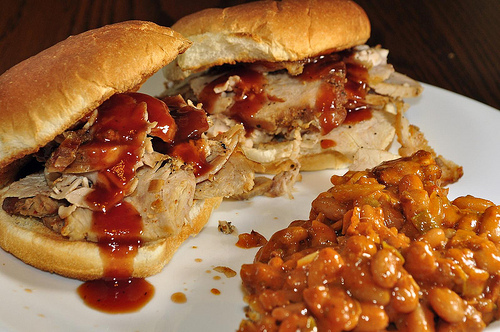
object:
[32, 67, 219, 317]
bbq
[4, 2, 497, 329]
dinner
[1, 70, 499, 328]
plate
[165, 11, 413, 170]
sandwich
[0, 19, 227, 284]
sandwich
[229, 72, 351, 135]
bbq pork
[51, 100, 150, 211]
bbq pork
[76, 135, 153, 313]
barbecue sauce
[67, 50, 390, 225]
meat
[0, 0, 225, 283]
bread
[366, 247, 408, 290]
bean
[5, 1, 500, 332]
table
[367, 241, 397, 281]
bean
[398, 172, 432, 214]
bean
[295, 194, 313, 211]
rice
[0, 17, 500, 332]
food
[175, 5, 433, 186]
bun set